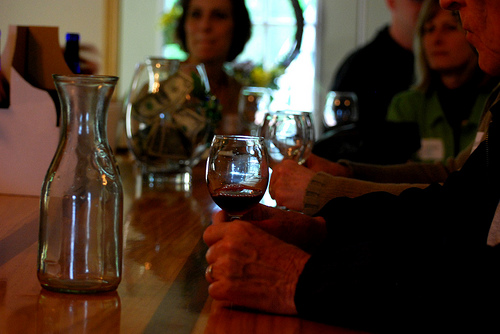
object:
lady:
[164, 3, 256, 153]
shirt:
[294, 99, 500, 334]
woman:
[388, 0, 493, 158]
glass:
[205, 134, 269, 220]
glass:
[258, 110, 309, 169]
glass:
[321, 90, 357, 128]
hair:
[174, 0, 251, 61]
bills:
[136, 73, 206, 161]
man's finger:
[204, 261, 228, 283]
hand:
[268, 159, 317, 211]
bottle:
[37, 73, 124, 294]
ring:
[206, 263, 217, 282]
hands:
[201, 220, 310, 317]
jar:
[120, 57, 219, 173]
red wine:
[210, 188, 262, 213]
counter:
[0, 161, 351, 334]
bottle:
[62, 33, 80, 77]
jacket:
[383, 80, 494, 162]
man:
[201, 0, 500, 334]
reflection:
[71, 192, 91, 281]